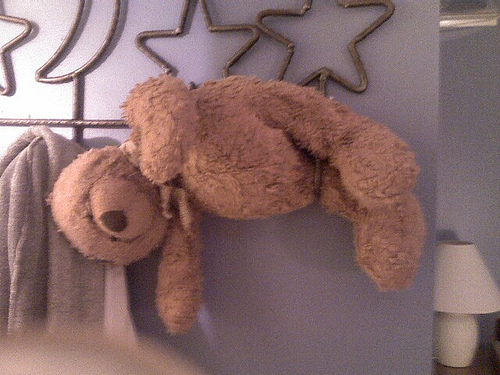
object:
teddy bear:
[43, 70, 427, 338]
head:
[44, 145, 169, 269]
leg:
[321, 166, 425, 292]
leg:
[281, 82, 418, 210]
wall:
[1, 0, 440, 373]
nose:
[99, 210, 127, 232]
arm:
[120, 73, 202, 186]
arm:
[154, 209, 206, 336]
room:
[0, 0, 500, 375]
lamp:
[431, 240, 499, 368]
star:
[254, 0, 395, 93]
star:
[134, 0, 260, 79]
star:
[0, 1, 32, 96]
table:
[431, 347, 500, 375]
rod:
[0, 0, 393, 202]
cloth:
[0, 125, 105, 341]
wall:
[432, 28, 498, 348]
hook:
[313, 74, 325, 202]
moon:
[34, 0, 123, 84]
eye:
[87, 214, 93, 221]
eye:
[111, 236, 118, 242]